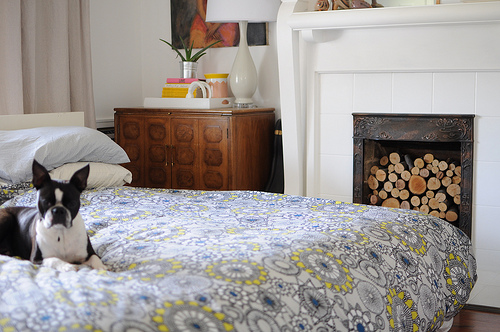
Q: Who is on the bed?
A: Dog.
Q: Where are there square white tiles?
A: Around fireplace.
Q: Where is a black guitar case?
A: Side of wood cabinet.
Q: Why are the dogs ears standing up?
A: Paying attention.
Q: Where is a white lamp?
A: On top of cabinet.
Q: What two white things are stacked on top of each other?
A: Pillows.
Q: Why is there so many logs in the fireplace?
A: Storage.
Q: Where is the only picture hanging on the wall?
A: Behind lamp.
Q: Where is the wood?
A: In the fireplace.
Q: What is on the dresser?
A: A vase.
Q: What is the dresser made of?
A: Wood.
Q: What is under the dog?
A: A bedspread.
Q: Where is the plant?
A: In a pot.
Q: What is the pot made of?
A: Metal.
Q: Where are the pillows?
A: Behind the dog.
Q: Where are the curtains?
A: Behind the bed.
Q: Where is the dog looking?
A: At the camera.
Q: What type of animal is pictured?
A: Dog?.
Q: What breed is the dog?
A: Boston terrier.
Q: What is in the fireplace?
A: Wood.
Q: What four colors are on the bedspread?
A: Blue, white, yellow and black.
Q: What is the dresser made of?
A: Wood.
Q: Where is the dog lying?
A: On the bed.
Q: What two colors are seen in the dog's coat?
A: Black and white.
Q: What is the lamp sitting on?
A: Dresser.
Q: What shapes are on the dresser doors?
A: Squares.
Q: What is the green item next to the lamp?
A: Plant.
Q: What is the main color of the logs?
A: Brown.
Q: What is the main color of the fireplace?
A: Black.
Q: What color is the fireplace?
A: White.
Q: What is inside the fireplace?
A: Wood.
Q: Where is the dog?
A: Bed.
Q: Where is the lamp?
A: On the cabinet.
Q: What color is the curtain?
A: Beige.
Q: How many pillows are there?
A: Two.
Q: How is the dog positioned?
A: Laying down.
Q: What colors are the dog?
A: White and black.